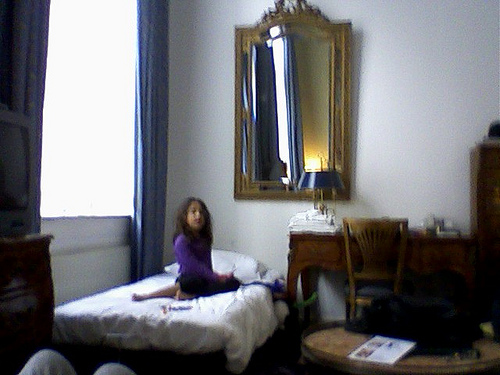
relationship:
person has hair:
[135, 197, 240, 302] [170, 196, 212, 249]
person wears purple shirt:
[135, 197, 240, 302] [173, 229, 213, 276]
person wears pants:
[135, 197, 240, 302] [179, 274, 241, 297]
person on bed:
[129, 197, 241, 305] [144, 268, 244, 360]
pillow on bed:
[172, 241, 256, 280] [47, 247, 292, 374]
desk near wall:
[283, 230, 481, 320] [367, 15, 462, 199]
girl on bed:
[168, 192, 242, 297] [47, 247, 292, 374]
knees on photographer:
[216, 262, 250, 312] [133, 145, 270, 303]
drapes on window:
[126, 5, 184, 283] [43, 2, 166, 227]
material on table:
[346, 332, 416, 368] [301, 322, 498, 372]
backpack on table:
[355, 286, 485, 353] [302, 307, 497, 373]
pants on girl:
[168, 267, 245, 297] [150, 193, 240, 295]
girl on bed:
[130, 195, 241, 302] [52, 256, 297, 373]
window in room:
[40, 0, 140, 220] [0, 0, 500, 372]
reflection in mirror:
[255, 23, 302, 185] [230, 0, 354, 204]